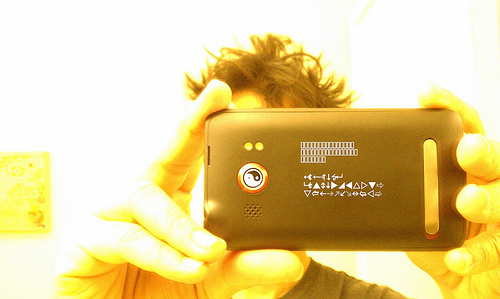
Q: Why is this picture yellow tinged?
A: Bad lighting.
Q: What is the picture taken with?
A: A cell phone.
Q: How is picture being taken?
A: Reflection in mirror.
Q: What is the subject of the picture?
A: Young man.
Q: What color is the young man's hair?
A: Brown.